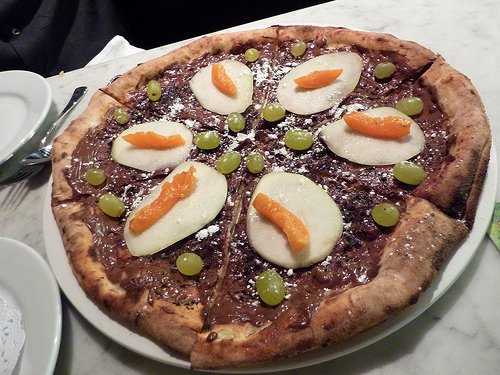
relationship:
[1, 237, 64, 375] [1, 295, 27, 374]
plate with doily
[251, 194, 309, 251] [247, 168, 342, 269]
orange puree on white slice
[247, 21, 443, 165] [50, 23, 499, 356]
slice of pizza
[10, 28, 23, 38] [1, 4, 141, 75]
button on a shirt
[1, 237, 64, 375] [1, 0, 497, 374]
plate on table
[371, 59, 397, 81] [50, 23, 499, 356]
grape on pizza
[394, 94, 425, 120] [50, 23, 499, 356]
grape on pizza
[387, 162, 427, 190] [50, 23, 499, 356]
grape on pizza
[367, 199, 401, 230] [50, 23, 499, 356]
grape on pizza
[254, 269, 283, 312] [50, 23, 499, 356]
grape on pizza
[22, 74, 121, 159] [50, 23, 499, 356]
spoon next to pizza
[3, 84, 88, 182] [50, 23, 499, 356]
fork next to pizza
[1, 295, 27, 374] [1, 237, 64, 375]
doily on plate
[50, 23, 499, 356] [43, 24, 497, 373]
pizza on plate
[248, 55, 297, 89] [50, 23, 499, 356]
white powder on pizza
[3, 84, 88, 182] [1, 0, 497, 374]
fork on table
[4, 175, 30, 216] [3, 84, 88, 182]
shadow of fork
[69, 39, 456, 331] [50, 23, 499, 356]
sauce on pizza